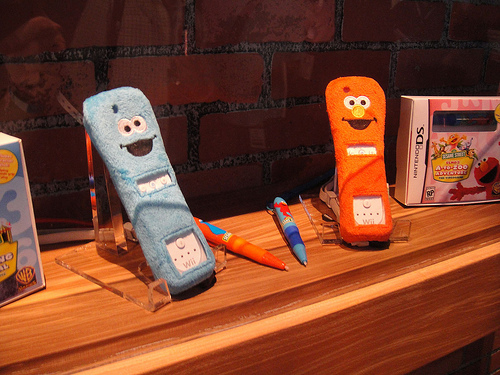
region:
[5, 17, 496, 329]
A display case for a video game.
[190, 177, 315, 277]
Two stylus pens.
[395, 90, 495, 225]
A Nintendo DS game.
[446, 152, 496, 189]
Elmo from Sesame Street.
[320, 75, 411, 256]
A Nintendo Wii controller.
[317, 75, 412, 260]
An Elmo covering for the controller.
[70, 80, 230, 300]
A Cookie Monster covering for the controller.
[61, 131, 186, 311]
A plastic stand for the controller.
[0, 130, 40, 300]
A Nintendo Wii game.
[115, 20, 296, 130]
A brick wall.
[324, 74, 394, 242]
the wii control has an orange cloth cover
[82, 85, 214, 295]
the wii controller has a blue cloth cover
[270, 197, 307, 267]
a blue, purple and orange pen is on the wooden table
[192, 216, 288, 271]
an orange and blue pen sits on top of a wooden table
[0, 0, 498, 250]
there is a red brick wall behind the table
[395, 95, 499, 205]
a nintendo DS game is on the wooden table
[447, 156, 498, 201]
a picture of sesame street elmo is on the nintendo game box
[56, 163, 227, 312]
the wii controllers are leaning against a plastic holder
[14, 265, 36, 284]
there's a warner brothers logo on the game box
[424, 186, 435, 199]
the nintendo DS game has a rating of RP rating pending logo on the box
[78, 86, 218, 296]
blue fuzzy cover on controller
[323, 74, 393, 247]
orange fuzzy cover on controller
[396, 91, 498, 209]
pink DS box near orange controller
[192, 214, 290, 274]
orange pen near blue controller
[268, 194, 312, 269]
blue pen near orange controller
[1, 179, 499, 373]
wooden shelf holding items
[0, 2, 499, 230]
brick wall behind shelf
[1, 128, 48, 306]
blue box near blue controller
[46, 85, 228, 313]
clear stand for controller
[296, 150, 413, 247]
clear stand for orange controller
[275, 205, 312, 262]
A colorful pen with blue as its base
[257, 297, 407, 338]
A wooden table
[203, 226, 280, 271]
A ball pen with orange color as its base color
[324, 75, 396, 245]
A toy phone with an orange cover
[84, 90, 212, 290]
a toy phone with a baby blue cover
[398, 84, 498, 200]
A toy box with Sesame Street characters...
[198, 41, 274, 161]
A red brick wall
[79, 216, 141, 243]
A plug for power connection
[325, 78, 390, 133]
A pattern designed after a character of Sesame Street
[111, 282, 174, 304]
A clear plastic stand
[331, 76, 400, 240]
Elmo sleeve on wii remote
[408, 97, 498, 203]
Nintendo DS game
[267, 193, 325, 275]
Elmo pen on ledge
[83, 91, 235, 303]
Cookie monster sleeve on wii remote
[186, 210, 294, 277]
Cookie monster pen on ledge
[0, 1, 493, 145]
Brick wall behind ledge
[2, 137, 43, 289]
Warner brothers game in corner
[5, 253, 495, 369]
A wood ledge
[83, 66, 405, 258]
Two kid wii remotes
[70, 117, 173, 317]
A clear wii remote holder